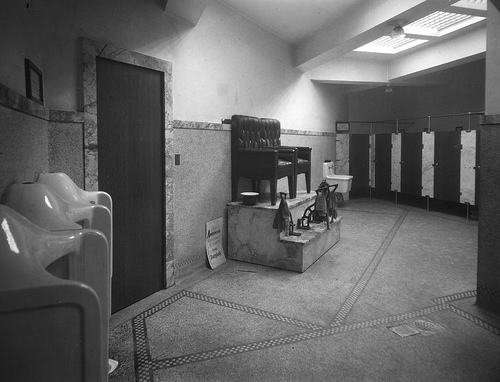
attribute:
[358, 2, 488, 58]
lights — on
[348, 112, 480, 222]
stalls — row, closed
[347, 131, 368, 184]
stall — row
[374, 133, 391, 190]
stall — row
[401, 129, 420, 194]
stall — row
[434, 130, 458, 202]
stall — row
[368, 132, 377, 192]
stall — bathroom, four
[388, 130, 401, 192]
stall — bathroom, four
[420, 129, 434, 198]
stall — bathroom, four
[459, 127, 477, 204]
stall — bathroom, four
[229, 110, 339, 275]
station — shoe shining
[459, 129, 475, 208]
door — stalls, white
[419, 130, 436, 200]
door — white, stalls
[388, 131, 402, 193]
door — stalls, white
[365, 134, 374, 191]
door — white, stalls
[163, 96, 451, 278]
station — shoe shining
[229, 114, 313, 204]
seats — shoe shine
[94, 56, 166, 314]
door — dark brown, wooden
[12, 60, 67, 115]
sign — maximum, capacity , information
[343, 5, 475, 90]
lights — on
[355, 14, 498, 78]
exhaust fan — exit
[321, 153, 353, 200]
tub basin — mensroom, white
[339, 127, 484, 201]
stalls — bathroom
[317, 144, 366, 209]
sink — short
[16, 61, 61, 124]
certificate — cleanliness